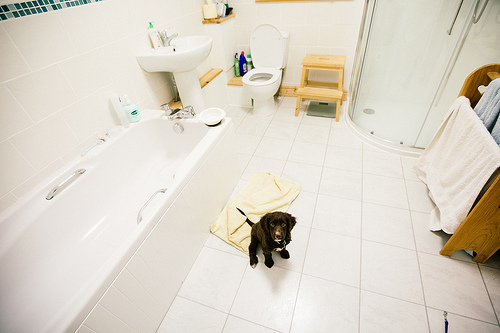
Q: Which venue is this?
A: This is a bathroom.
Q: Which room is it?
A: It is a bathroom.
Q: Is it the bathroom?
A: Yes, it is the bathroom.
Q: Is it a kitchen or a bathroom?
A: It is a bathroom.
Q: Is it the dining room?
A: No, it is the bathroom.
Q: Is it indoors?
A: Yes, it is indoors.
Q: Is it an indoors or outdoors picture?
A: It is indoors.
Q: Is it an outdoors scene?
A: No, it is indoors.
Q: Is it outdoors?
A: No, it is indoors.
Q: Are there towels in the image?
A: Yes, there is a towel.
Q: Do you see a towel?
A: Yes, there is a towel.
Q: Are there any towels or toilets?
A: Yes, there is a towel.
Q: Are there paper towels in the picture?
A: No, there are no paper towels.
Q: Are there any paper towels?
A: No, there are no paper towels.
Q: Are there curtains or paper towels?
A: No, there are no paper towels or curtains.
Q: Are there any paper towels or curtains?
A: No, there are no paper towels or curtains.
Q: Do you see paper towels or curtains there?
A: No, there are no paper towels or curtains.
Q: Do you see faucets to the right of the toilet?
A: No, the faucet is to the left of the toilet.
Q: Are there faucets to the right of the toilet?
A: No, the faucet is to the left of the toilet.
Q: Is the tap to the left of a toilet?
A: Yes, the tap is to the left of a toilet.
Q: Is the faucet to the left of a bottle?
A: No, the faucet is to the left of a toilet.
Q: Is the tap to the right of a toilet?
A: No, the tap is to the left of a toilet.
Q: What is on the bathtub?
A: The faucet is on the bath tub.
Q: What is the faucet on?
A: The faucet is on the bath tub.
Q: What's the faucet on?
A: The faucet is on the bath tub.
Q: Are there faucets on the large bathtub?
A: Yes, there is a faucet on the tub.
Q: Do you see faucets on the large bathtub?
A: Yes, there is a faucet on the tub.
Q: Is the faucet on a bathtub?
A: Yes, the faucet is on a bathtub.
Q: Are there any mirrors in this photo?
A: No, there are no mirrors.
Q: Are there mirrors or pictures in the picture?
A: No, there are no mirrors or pictures.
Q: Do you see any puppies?
A: Yes, there is a puppy.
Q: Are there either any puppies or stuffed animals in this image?
A: Yes, there is a puppy.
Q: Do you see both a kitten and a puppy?
A: No, there is a puppy but no kittens.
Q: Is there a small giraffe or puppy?
A: Yes, there is a small puppy.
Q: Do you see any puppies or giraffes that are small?
A: Yes, the puppy is small.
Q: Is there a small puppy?
A: Yes, there is a small puppy.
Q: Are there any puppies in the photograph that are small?
A: Yes, there is a puppy that is small.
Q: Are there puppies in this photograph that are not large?
A: Yes, there is a small puppy.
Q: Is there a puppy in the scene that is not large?
A: Yes, there is a small puppy.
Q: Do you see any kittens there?
A: No, there are no kittens.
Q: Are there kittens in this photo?
A: No, there are no kittens.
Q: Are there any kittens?
A: No, there are no kittens.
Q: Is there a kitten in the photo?
A: No, there are no kittens.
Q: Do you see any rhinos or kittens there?
A: No, there are no kittens or rhinos.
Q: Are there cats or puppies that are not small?
A: No, there is a puppy but it is small.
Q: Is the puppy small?
A: Yes, the puppy is small.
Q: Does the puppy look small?
A: Yes, the puppy is small.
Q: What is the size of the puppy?
A: The puppy is small.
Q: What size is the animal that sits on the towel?
A: The puppy is small.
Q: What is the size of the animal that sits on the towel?
A: The puppy is small.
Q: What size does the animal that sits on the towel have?
A: The puppy has small size.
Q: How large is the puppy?
A: The puppy is small.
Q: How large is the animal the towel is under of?
A: The puppy is small.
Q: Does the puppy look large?
A: No, the puppy is small.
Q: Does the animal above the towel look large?
A: No, the puppy is small.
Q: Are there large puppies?
A: No, there is a puppy but it is small.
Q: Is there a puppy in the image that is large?
A: No, there is a puppy but it is small.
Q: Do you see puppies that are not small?
A: No, there is a puppy but it is small.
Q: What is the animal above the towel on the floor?
A: The animal is a puppy.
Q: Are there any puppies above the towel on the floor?
A: Yes, there is a puppy above the towel.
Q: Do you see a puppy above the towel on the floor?
A: Yes, there is a puppy above the towel.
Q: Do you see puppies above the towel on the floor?
A: Yes, there is a puppy above the towel.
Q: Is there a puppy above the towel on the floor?
A: Yes, there is a puppy above the towel.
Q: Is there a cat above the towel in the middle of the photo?
A: No, there is a puppy above the towel.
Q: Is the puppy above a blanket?
A: No, the puppy is above the towel.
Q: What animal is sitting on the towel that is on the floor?
A: The animal is a puppy.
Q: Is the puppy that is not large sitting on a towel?
A: Yes, the puppy is sitting on a towel.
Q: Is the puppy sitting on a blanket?
A: No, the puppy is sitting on a towel.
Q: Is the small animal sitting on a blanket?
A: No, the puppy is sitting on a towel.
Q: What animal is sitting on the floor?
A: The puppy is sitting on the floor.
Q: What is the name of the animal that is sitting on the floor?
A: The animal is a puppy.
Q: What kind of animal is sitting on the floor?
A: The animal is a puppy.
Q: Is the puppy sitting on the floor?
A: Yes, the puppy is sitting on the floor.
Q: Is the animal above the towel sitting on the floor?
A: Yes, the puppy is sitting on the floor.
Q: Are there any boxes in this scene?
A: No, there are no boxes.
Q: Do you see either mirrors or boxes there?
A: No, there are no boxes or mirrors.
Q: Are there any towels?
A: Yes, there is a towel.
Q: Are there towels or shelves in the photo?
A: Yes, there is a towel.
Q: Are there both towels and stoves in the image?
A: No, there is a towel but no stoves.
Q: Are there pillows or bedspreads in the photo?
A: No, there are no pillows or bedspreads.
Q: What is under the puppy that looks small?
A: The towel is under the puppy.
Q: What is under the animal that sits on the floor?
A: The towel is under the puppy.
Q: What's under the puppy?
A: The towel is under the puppy.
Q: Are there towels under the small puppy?
A: Yes, there is a towel under the puppy.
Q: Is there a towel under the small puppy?
A: Yes, there is a towel under the puppy.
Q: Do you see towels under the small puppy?
A: Yes, there is a towel under the puppy.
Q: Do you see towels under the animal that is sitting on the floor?
A: Yes, there is a towel under the puppy.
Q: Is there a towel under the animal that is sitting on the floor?
A: Yes, there is a towel under the puppy.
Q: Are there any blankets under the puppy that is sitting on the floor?
A: No, there is a towel under the puppy.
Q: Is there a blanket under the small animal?
A: No, there is a towel under the puppy.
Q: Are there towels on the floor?
A: Yes, there is a towel on the floor.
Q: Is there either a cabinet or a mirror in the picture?
A: No, there are no mirrors or cabinets.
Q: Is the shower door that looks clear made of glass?
A: Yes, the shower door is made of glass.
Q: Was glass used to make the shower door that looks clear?
A: Yes, the shower door is made of glass.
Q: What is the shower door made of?
A: The shower door is made of glass.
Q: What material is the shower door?
A: The shower door is made of glass.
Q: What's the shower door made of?
A: The shower door is made of glass.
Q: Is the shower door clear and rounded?
A: Yes, the shower door is clear and rounded.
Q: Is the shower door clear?
A: Yes, the shower door is clear.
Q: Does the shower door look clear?
A: Yes, the shower door is clear.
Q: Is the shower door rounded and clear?
A: Yes, the shower door is rounded and clear.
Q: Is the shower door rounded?
A: Yes, the shower door is rounded.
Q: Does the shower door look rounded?
A: Yes, the shower door is rounded.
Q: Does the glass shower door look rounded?
A: Yes, the shower door is rounded.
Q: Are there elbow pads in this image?
A: No, there are no elbow pads.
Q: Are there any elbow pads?
A: No, there are no elbow pads.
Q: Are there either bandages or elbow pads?
A: No, there are no elbow pads or bandages.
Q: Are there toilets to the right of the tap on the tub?
A: Yes, there is a toilet to the right of the tap.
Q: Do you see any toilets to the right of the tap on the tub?
A: Yes, there is a toilet to the right of the tap.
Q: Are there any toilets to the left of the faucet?
A: No, the toilet is to the right of the faucet.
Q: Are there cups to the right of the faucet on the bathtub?
A: No, there is a toilet to the right of the faucet.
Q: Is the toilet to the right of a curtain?
A: No, the toilet is to the right of the tap.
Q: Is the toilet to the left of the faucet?
A: No, the toilet is to the right of the faucet.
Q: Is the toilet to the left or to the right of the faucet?
A: The toilet is to the right of the faucet.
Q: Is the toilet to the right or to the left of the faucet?
A: The toilet is to the right of the faucet.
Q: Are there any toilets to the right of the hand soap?
A: Yes, there is a toilet to the right of the hand soap.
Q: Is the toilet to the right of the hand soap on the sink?
A: Yes, the toilet is to the right of the hand soap.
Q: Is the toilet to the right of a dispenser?
A: No, the toilet is to the right of the hand soap.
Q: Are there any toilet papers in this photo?
A: No, there are no toilet papers.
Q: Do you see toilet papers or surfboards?
A: No, there are no toilet papers or surfboards.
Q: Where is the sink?
A: The sink is in the bathroom.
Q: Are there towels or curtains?
A: Yes, there is a towel.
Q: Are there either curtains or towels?
A: Yes, there is a towel.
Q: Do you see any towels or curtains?
A: Yes, there is a towel.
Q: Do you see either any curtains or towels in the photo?
A: Yes, there is a towel.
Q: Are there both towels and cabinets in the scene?
A: No, there is a towel but no cabinets.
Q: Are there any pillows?
A: No, there are no pillows.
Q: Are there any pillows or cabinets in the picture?
A: No, there are no pillows or cabinets.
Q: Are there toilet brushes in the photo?
A: No, there are no toilet brushes.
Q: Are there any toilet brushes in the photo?
A: No, there are no toilet brushes.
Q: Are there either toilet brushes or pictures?
A: No, there are no toilet brushes or pictures.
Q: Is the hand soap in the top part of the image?
A: Yes, the hand soap is in the top of the image.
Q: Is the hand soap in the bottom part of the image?
A: No, the hand soap is in the top of the image.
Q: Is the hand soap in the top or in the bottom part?
A: The hand soap is in the top of the image.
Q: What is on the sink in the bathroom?
A: The hand soap is on the sink.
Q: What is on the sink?
A: The hand soap is on the sink.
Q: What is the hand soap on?
A: The hand soap is on the sink.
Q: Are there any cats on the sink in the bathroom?
A: No, there is a hand soap on the sink.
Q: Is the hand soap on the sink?
A: Yes, the hand soap is on the sink.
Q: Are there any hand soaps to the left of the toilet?
A: Yes, there is a hand soap to the left of the toilet.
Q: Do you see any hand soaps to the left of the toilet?
A: Yes, there is a hand soap to the left of the toilet.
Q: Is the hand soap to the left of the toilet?
A: Yes, the hand soap is to the left of the toilet.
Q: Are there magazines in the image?
A: No, there are no magazines.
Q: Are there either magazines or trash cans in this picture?
A: No, there are no magazines or trash cans.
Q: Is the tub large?
A: Yes, the tub is large.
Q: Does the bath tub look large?
A: Yes, the bath tub is large.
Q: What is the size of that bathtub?
A: The bathtub is large.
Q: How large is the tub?
A: The tub is large.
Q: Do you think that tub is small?
A: No, the tub is large.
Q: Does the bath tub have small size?
A: No, the bath tub is large.